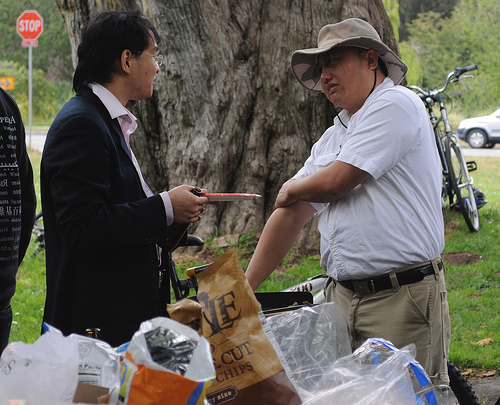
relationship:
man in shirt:
[244, 17, 448, 392] [289, 75, 470, 290]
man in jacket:
[39, 10, 208, 349] [31, 78, 180, 343]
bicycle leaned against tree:
[398, 53, 496, 239] [53, 3, 433, 275]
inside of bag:
[140, 323, 198, 379] [96, 296, 221, 402]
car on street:
[449, 104, 498, 155] [3, 140, 497, 156]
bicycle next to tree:
[394, 64, 490, 234] [53, 3, 433, 275]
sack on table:
[236, 293, 452, 402] [0, 353, 484, 403]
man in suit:
[39, 10, 208, 349] [32, 78, 180, 351]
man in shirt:
[244, 17, 448, 392] [290, 71, 450, 292]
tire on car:
[464, 125, 489, 148] [450, 107, 497, 151]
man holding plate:
[39, 10, 208, 349] [188, 175, 262, 209]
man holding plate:
[58, 6, 178, 138] [191, 182, 270, 212]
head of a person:
[298, 14, 408, 134] [278, 14, 466, 232]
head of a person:
[59, 3, 183, 142] [50, 10, 194, 237]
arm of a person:
[309, 125, 396, 215] [275, 11, 438, 220]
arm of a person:
[241, 180, 332, 327] [253, 13, 424, 207]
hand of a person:
[156, 180, 215, 242] [51, 0, 211, 203]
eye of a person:
[322, 51, 341, 71] [283, 10, 408, 190]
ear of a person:
[365, 50, 379, 71] [297, 8, 403, 149]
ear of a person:
[361, 41, 387, 81] [283, 10, 408, 190]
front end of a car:
[453, 104, 491, 147] [453, 100, 499, 141]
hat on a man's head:
[283, 14, 417, 78] [284, 8, 403, 126]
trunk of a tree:
[64, 2, 433, 297] [53, 3, 433, 275]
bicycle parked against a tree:
[394, 64, 490, 234] [66, 2, 408, 262]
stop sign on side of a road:
[10, 5, 50, 59] [10, 122, 64, 152]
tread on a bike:
[448, 360, 463, 378] [428, 354, 475, 400]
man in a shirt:
[264, 9, 419, 175] [292, 77, 459, 295]